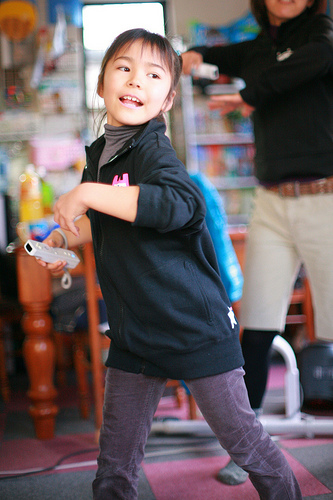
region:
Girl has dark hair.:
[114, 29, 240, 113]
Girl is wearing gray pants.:
[97, 411, 172, 487]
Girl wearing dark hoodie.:
[108, 251, 202, 329]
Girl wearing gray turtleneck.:
[96, 120, 125, 156]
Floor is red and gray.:
[119, 454, 166, 498]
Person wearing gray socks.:
[216, 448, 232, 493]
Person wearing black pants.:
[250, 364, 263, 411]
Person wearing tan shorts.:
[249, 224, 313, 308]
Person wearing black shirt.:
[269, 127, 304, 171]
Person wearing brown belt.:
[281, 173, 319, 187]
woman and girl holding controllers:
[8, 0, 329, 274]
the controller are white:
[1, 0, 321, 351]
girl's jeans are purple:
[88, 330, 310, 488]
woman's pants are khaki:
[235, 149, 332, 330]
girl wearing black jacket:
[68, 131, 246, 402]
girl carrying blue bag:
[166, 156, 263, 301]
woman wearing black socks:
[241, 308, 299, 429]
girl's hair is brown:
[94, 20, 171, 121]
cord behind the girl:
[3, 416, 125, 496]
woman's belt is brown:
[256, 160, 331, 197]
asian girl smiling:
[74, 35, 206, 134]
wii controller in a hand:
[17, 217, 88, 309]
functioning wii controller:
[26, 230, 114, 295]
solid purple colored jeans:
[194, 343, 325, 498]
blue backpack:
[166, 152, 264, 307]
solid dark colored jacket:
[66, 122, 284, 396]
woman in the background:
[195, 10, 331, 307]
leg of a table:
[7, 167, 71, 436]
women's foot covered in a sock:
[203, 406, 275, 483]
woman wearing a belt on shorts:
[233, 163, 331, 213]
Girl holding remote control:
[23, 232, 91, 292]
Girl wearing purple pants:
[70, 342, 316, 493]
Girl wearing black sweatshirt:
[69, 119, 223, 276]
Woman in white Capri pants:
[248, 199, 323, 366]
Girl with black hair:
[100, 27, 180, 104]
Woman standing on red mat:
[200, 398, 301, 498]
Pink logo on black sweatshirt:
[100, 170, 135, 191]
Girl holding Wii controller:
[20, 233, 106, 280]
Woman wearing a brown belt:
[261, 167, 331, 203]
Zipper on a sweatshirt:
[218, 301, 245, 325]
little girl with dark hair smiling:
[93, 26, 184, 128]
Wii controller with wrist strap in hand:
[14, 221, 83, 290]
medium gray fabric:
[99, 377, 160, 441]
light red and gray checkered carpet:
[291, 440, 329, 472]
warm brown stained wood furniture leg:
[20, 317, 60, 442]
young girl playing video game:
[20, 27, 229, 393]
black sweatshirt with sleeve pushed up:
[48, 173, 203, 242]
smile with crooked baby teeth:
[114, 91, 147, 110]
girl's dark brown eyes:
[110, 55, 168, 81]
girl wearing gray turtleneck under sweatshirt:
[82, 121, 176, 165]